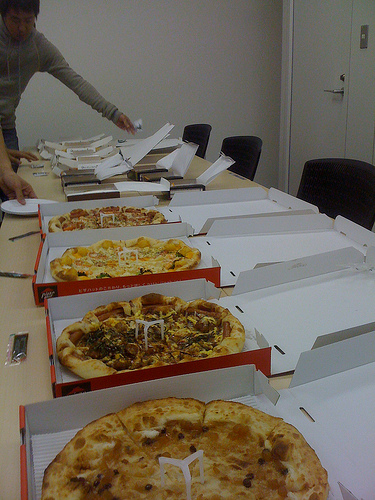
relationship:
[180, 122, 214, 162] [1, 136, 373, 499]
chair at table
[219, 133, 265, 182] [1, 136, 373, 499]
chair at table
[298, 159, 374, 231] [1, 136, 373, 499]
chair at table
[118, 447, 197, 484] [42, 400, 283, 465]
cheese on pizza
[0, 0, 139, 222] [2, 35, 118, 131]
man wearing shirt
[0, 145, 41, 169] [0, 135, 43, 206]
hand holding hand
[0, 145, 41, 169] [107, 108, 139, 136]
hand holding hand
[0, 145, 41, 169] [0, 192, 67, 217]
hand holding plate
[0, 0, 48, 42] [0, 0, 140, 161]
head of a man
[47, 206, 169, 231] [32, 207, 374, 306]
pizza in box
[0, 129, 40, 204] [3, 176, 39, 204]
man has hand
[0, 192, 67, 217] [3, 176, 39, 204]
plate in hand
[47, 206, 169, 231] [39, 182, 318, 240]
pizza in box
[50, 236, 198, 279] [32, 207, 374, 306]
pizza in box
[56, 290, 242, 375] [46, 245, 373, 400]
pizza in box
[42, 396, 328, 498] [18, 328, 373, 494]
pizza in box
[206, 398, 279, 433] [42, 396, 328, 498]
crust of pizza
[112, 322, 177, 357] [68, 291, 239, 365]
toppings on top of pizza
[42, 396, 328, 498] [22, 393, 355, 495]
pizza in box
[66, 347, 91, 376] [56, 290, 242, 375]
crust of pizza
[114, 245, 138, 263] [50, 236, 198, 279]
object in pizza